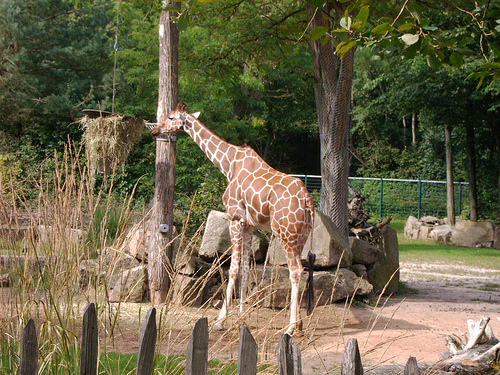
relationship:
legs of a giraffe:
[212, 224, 260, 333] [143, 98, 320, 343]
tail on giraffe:
[302, 195, 317, 317] [143, 98, 320, 343]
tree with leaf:
[182, 2, 478, 282] [333, 32, 354, 56]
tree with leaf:
[182, 2, 478, 282] [306, 23, 327, 38]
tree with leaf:
[182, 2, 478, 282] [397, 20, 413, 35]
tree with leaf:
[182, 2, 478, 282] [452, 34, 476, 46]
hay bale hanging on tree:
[80, 112, 144, 182] [145, 2, 181, 303]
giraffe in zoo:
[143, 98, 320, 343] [2, 2, 496, 373]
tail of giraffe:
[302, 195, 317, 317] [143, 98, 320, 343]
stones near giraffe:
[1, 200, 401, 307] [143, 98, 320, 343]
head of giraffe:
[138, 98, 199, 140] [133, 93, 325, 336]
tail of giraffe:
[290, 195, 324, 312] [148, 97, 395, 337]